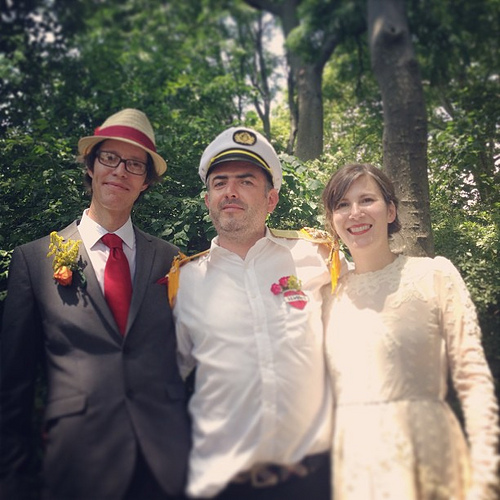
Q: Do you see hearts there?
A: Yes, there is a heart.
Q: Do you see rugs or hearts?
A: Yes, there is a heart.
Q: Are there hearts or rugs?
A: Yes, there is a heart.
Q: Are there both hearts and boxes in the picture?
A: No, there is a heart but no boxes.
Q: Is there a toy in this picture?
A: No, there are no toys.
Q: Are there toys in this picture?
A: No, there are no toys.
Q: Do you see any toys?
A: No, there are no toys.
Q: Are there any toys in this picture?
A: No, there are no toys.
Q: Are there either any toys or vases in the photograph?
A: No, there are no toys or vases.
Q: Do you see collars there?
A: Yes, there is a collar.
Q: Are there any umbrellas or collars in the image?
A: Yes, there is a collar.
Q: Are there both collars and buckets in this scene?
A: No, there is a collar but no buckets.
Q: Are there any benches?
A: No, there are no benches.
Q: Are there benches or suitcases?
A: No, there are no benches or suitcases.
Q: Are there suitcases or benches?
A: No, there are no benches or suitcases.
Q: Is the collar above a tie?
A: Yes, the collar is above a tie.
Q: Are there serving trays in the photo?
A: No, there are no serving trays.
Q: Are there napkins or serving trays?
A: No, there are no serving trays or napkins.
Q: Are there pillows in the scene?
A: No, there are no pillows.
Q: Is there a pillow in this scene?
A: No, there are no pillows.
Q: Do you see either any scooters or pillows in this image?
A: No, there are no pillows or scooters.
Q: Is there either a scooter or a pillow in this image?
A: No, there are no pillows or scooters.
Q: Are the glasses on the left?
A: Yes, the glasses are on the left of the image.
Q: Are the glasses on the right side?
A: No, the glasses are on the left of the image.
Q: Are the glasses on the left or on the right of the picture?
A: The glasses are on the left of the image.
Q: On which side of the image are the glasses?
A: The glasses are on the left of the image.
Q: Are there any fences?
A: No, there are no fences.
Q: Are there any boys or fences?
A: No, there are no fences or boys.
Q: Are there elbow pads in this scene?
A: No, there are no elbow pads.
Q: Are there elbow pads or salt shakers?
A: No, there are no elbow pads or salt shakers.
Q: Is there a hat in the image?
A: Yes, there is a hat.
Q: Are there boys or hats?
A: Yes, there is a hat.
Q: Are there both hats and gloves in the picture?
A: No, there is a hat but no gloves.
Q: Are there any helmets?
A: No, there are no helmets.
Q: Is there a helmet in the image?
A: No, there are no helmets.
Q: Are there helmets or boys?
A: No, there are no helmets or boys.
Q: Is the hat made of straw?
A: Yes, the hat is made of straw.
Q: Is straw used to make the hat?
A: Yes, the hat is made of straw.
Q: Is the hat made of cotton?
A: No, the hat is made of straw.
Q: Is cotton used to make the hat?
A: No, the hat is made of straw.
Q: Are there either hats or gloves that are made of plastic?
A: No, there is a hat but it is made of straw.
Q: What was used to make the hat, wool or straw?
A: The hat is made of straw.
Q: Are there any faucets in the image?
A: No, there are no faucets.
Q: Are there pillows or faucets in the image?
A: No, there are no faucets or pillows.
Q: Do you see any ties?
A: Yes, there is a tie.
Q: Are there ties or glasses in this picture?
A: Yes, there is a tie.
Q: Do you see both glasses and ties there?
A: Yes, there are both a tie and glasses.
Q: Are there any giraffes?
A: No, there are no giraffes.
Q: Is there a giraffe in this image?
A: No, there are no giraffes.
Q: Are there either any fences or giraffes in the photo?
A: No, there are no giraffes or fences.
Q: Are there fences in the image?
A: No, there are no fences.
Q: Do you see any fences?
A: No, there are no fences.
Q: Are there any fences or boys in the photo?
A: No, there are no fences or boys.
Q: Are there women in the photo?
A: Yes, there is a woman.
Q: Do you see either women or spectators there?
A: Yes, there is a woman.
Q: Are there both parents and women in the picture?
A: No, there is a woman but no parents.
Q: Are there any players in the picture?
A: No, there are no players.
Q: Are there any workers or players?
A: No, there are no players or workers.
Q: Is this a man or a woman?
A: This is a woman.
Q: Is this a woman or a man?
A: This is a woman.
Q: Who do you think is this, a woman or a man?
A: This is a woman.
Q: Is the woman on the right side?
A: Yes, the woman is on the right of the image.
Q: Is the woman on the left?
A: No, the woman is on the right of the image.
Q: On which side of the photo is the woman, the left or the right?
A: The woman is on the right of the image.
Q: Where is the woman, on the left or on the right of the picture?
A: The woman is on the right of the image.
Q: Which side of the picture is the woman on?
A: The woman is on the right of the image.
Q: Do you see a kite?
A: No, there are no kites.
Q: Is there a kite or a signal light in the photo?
A: No, there are no kites or traffic lights.